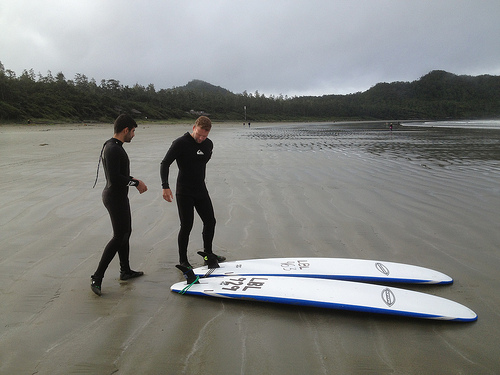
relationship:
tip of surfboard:
[465, 306, 475, 325] [171, 260, 481, 327]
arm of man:
[203, 142, 211, 183] [158, 114, 231, 277]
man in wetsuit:
[158, 114, 231, 277] [159, 130, 220, 263]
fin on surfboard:
[174, 261, 201, 284] [171, 260, 481, 327]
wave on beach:
[415, 114, 500, 126] [3, 119, 500, 374]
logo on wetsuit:
[196, 148, 206, 157] [159, 130, 220, 263]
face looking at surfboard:
[193, 127, 207, 146] [171, 260, 481, 327]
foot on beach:
[89, 272, 104, 296] [3, 119, 500, 374]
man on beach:
[158, 114, 231, 277] [3, 119, 500, 374]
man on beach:
[85, 111, 157, 301] [3, 119, 500, 374]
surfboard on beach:
[171, 260, 481, 327] [3, 119, 500, 374]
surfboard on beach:
[182, 249, 455, 288] [3, 119, 500, 374]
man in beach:
[158, 114, 231, 277] [3, 119, 500, 374]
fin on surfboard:
[196, 245, 226, 271] [182, 249, 455, 288]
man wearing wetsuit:
[158, 114, 231, 277] [159, 130, 220, 263]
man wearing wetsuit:
[85, 111, 157, 301] [91, 135, 151, 278]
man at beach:
[158, 114, 231, 277] [3, 119, 500, 374]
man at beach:
[85, 111, 157, 301] [3, 119, 500, 374]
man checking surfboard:
[158, 114, 231, 277] [171, 260, 481, 327]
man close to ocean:
[158, 114, 231, 277] [402, 107, 500, 153]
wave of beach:
[415, 114, 500, 126] [3, 119, 500, 374]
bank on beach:
[2, 104, 379, 127] [3, 119, 500, 374]